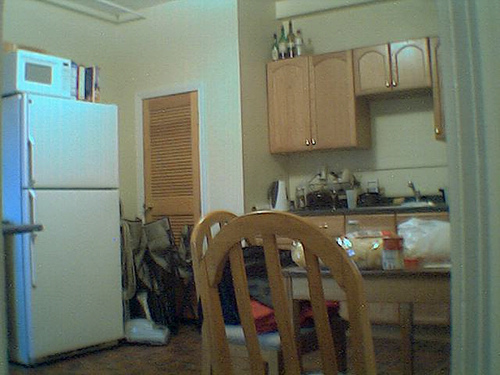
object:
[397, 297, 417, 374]
stand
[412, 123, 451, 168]
sky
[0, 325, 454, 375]
floor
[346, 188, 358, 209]
cup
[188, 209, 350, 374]
chair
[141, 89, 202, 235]
door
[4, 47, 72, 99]
microwave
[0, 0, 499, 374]
wall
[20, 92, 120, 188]
door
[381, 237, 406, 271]
food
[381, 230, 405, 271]
can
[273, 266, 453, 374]
table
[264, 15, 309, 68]
wheel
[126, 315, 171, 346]
vacuum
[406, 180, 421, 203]
faucet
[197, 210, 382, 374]
chair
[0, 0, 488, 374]
kitchen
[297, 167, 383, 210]
clutter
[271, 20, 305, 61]
alcohol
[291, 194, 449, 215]
board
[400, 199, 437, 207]
sink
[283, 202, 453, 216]
counter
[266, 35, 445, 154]
cupboard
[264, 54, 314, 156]
door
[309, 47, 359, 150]
door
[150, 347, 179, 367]
part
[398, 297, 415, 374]
part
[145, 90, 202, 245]
water heater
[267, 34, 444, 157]
cabinets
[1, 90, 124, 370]
fridge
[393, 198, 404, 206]
sponge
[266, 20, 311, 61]
bottle